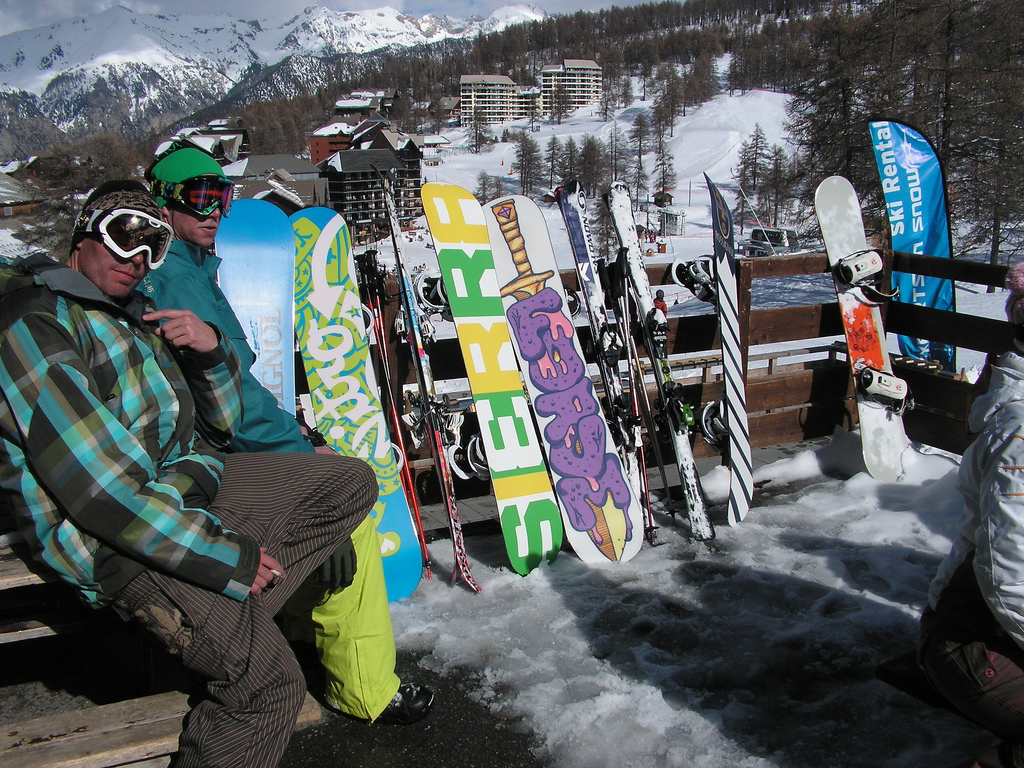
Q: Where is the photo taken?
A: Lodge.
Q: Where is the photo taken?
A: Ski slope.